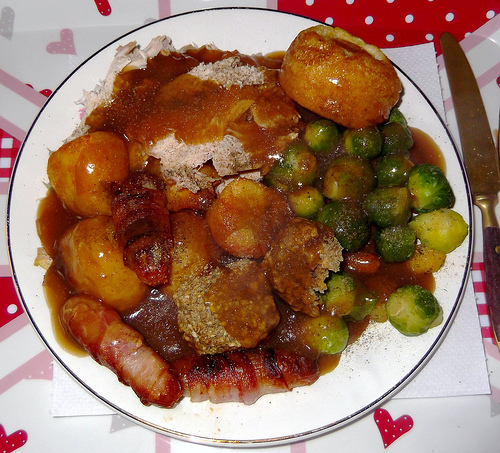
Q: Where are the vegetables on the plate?
A: To the right.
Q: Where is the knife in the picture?
A: Beside the plate.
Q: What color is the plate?
A: White.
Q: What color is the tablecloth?
A: Red and white.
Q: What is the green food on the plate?
A: Brussels sprouts.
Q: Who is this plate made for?
A: An adult.